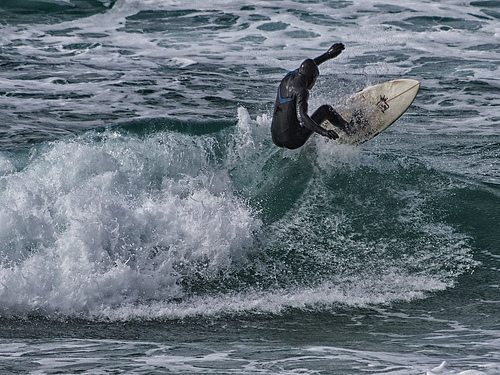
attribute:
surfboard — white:
[315, 78, 421, 146]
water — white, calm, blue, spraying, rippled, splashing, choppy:
[0, 1, 499, 375]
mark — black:
[375, 94, 389, 113]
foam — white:
[1, 1, 500, 375]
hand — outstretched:
[327, 43, 345, 59]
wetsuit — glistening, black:
[271, 43, 362, 149]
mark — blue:
[277, 69, 299, 104]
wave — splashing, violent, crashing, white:
[0, 114, 499, 322]